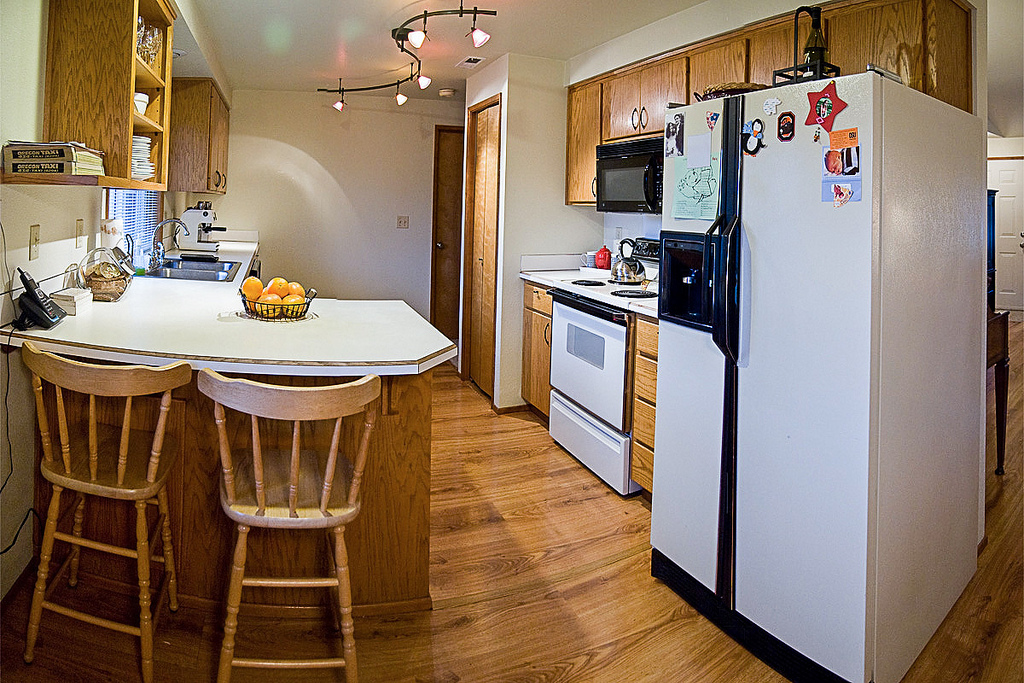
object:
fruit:
[243, 276, 306, 318]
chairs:
[14, 342, 379, 682]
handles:
[703, 212, 738, 362]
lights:
[329, 27, 490, 113]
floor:
[2, 360, 1024, 683]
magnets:
[740, 79, 861, 209]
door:
[550, 301, 626, 434]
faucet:
[151, 218, 190, 266]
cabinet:
[566, 82, 602, 206]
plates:
[131, 134, 156, 179]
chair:
[191, 369, 385, 682]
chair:
[24, 342, 193, 683]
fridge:
[647, 68, 981, 683]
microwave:
[594, 134, 663, 213]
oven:
[548, 289, 628, 496]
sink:
[145, 260, 243, 282]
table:
[0, 280, 458, 638]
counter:
[0, 275, 458, 378]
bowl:
[239, 287, 318, 324]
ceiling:
[175, 0, 819, 105]